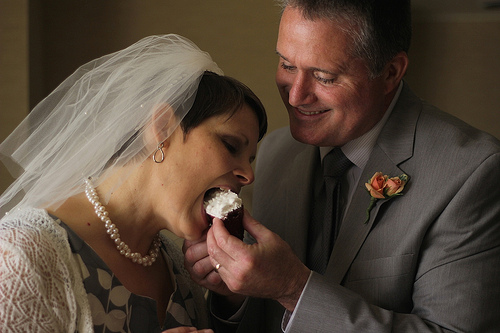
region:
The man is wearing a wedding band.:
[203, 248, 223, 271]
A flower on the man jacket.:
[353, 164, 427, 228]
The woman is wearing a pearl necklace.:
[77, 181, 167, 266]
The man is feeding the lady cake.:
[173, 163, 329, 300]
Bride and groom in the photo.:
[45, 15, 455, 277]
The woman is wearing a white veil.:
[50, 63, 222, 144]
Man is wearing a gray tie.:
[303, 141, 347, 263]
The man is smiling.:
[271, 70, 341, 160]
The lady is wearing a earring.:
[140, 133, 192, 173]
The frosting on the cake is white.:
[205, 188, 250, 217]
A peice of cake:
[204, 186, 244, 239]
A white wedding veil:
[0, 34, 227, 221]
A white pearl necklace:
[76, 176, 159, 268]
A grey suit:
[203, 77, 498, 332]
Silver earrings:
[151, 139, 166, 164]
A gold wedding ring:
[213, 260, 225, 272]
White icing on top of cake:
[200, 186, 242, 222]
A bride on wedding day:
[0, 32, 269, 332]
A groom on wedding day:
[203, 4, 498, 331]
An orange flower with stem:
[362, 169, 408, 224]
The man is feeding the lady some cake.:
[193, 20, 460, 314]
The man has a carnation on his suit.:
[361, 162, 411, 229]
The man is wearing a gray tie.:
[294, 150, 357, 250]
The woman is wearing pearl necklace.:
[72, 189, 162, 270]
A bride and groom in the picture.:
[83, 38, 450, 300]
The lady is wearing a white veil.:
[45, 32, 215, 147]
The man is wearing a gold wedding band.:
[189, 252, 239, 279]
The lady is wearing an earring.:
[132, 136, 179, 176]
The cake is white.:
[200, 190, 275, 220]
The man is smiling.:
[258, 29, 372, 156]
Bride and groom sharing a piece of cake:
[1, 1, 489, 331]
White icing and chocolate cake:
[198, 183, 250, 235]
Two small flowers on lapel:
[356, 170, 413, 232]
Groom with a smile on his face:
[267, 2, 412, 147]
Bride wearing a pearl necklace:
[65, 155, 176, 273]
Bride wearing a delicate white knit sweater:
[2, 198, 104, 329]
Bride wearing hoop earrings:
[150, 140, 170, 165]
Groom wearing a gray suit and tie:
[257, 115, 497, 330]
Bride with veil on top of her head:
[10, 6, 211, 246]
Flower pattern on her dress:
[52, 217, 188, 332]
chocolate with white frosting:
[200, 189, 255, 221]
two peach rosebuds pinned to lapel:
[367, 154, 415, 212]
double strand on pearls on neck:
[86, 174, 159, 278]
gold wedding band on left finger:
[207, 262, 238, 277]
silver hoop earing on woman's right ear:
[149, 135, 182, 176]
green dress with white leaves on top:
[83, 264, 130, 331]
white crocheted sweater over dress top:
[2, 222, 73, 315]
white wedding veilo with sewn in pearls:
[36, 48, 178, 141]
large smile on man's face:
[289, 90, 351, 132]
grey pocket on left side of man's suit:
[351, 243, 418, 307]